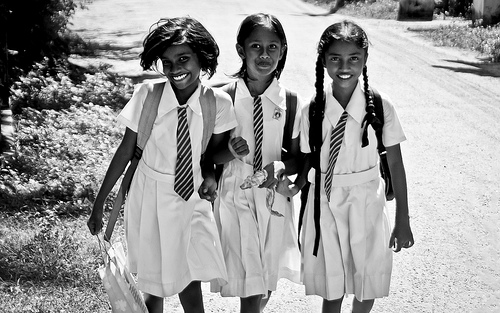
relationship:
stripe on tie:
[175, 114, 193, 178] [172, 105, 194, 201]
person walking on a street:
[198, 9, 306, 311] [411, 41, 497, 311]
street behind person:
[411, 41, 497, 311] [87, 14, 235, 311]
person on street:
[118, 14, 234, 295] [411, 41, 497, 311]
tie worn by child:
[321, 111, 348, 202] [295, 20, 417, 311]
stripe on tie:
[175, 162, 193, 179] [173, 106, 195, 199]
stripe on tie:
[256, 134, 263, 154] [173, 106, 195, 199]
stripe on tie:
[329, 136, 339, 156] [253, 95, 264, 174]